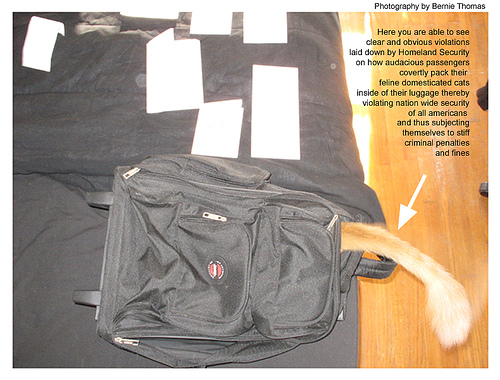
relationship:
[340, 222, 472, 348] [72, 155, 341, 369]
tail in suitcase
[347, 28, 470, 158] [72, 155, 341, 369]
text by suitcase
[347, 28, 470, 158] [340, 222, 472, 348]
text above tail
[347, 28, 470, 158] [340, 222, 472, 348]
text points at tail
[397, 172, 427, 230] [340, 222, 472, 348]
arrow pointing to tail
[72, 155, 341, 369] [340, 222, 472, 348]
suitcase has tail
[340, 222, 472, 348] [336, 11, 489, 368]
tail above floor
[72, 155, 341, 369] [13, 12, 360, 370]
suitcase on bed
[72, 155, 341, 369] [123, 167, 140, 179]
suitcase has zipper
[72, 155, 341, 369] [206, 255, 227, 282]
suitcase has logo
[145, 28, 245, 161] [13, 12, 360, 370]
papers on bed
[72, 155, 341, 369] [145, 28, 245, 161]
suitcase near papers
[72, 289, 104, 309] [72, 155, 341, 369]
foot of suitcase